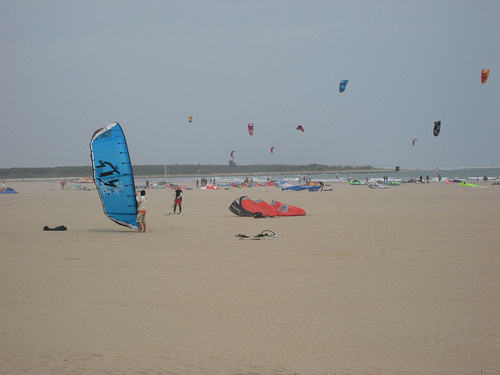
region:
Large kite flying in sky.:
[461, 55, 493, 132]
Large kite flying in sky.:
[421, 113, 451, 145]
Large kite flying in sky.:
[330, 70, 359, 103]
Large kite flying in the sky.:
[291, 117, 302, 129]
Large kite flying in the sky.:
[242, 119, 264, 139]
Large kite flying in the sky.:
[176, 105, 206, 135]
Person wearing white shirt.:
[137, 195, 157, 212]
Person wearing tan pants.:
[131, 205, 151, 220]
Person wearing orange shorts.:
[166, 197, 197, 202]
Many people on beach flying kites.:
[166, 145, 449, 223]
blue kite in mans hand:
[84, 117, 139, 241]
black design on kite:
[92, 154, 121, 194]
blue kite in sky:
[328, 70, 355, 102]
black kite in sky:
[426, 114, 448, 141]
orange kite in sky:
[474, 61, 495, 96]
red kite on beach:
[223, 186, 309, 225]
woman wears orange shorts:
[136, 208, 153, 217]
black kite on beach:
[36, 217, 82, 240]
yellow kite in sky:
[179, 108, 201, 128]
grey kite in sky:
[406, 127, 421, 159]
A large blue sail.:
[86, 117, 142, 232]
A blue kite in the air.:
[337, 75, 349, 95]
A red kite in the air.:
[477, 67, 493, 84]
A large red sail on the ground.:
[224, 195, 306, 220]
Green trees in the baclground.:
[0, 162, 384, 182]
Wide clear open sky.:
[1, 2, 498, 170]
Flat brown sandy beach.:
[1, 181, 497, 369]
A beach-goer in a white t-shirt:
[131, 187, 147, 229]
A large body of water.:
[5, 167, 497, 180]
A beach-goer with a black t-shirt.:
[168, 182, 183, 217]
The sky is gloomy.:
[30, 33, 241, 95]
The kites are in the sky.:
[158, 77, 497, 167]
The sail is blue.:
[66, 113, 156, 258]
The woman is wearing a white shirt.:
[128, 179, 158, 240]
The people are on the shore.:
[22, 154, 478, 242]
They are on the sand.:
[10, 168, 432, 360]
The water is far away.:
[67, 159, 480, 195]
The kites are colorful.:
[169, 46, 494, 189]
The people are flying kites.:
[90, 145, 493, 225]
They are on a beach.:
[26, 23, 477, 311]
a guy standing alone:
[131, 185, 157, 231]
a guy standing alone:
[132, 189, 149, 245]